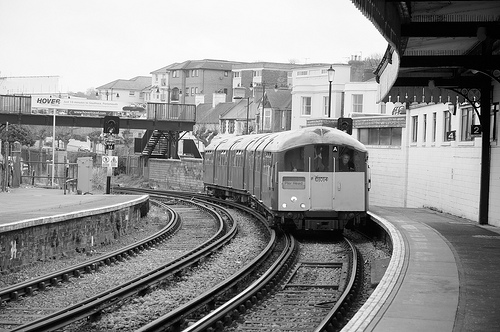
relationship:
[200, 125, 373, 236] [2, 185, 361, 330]
train on track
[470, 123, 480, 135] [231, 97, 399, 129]
number 2 on sign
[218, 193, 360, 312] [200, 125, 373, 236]
gravel under train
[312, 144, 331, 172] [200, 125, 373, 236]
window on train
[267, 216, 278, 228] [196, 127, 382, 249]
wheels on train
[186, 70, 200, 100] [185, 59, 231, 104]
windows on building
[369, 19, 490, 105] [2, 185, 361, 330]
awning over track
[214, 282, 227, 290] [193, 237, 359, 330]
rails on tracks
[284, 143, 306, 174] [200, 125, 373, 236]
window on front of train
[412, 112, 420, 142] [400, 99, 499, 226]
window on side of building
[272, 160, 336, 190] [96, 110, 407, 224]
sign on front of train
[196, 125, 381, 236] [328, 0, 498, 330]
train coming into station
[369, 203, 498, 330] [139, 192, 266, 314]
platform beside tracks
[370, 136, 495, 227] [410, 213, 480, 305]
wall alongside train platform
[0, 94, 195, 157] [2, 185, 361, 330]
bridge over track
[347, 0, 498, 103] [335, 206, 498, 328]
shelter over platform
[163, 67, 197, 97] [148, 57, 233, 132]
windows are on buildings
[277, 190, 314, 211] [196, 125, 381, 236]
lights are on train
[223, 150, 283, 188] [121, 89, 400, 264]
windows are on train.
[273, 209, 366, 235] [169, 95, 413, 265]
wheels are on train.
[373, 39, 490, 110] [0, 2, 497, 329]
awning over station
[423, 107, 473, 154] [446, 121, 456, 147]
sign has 4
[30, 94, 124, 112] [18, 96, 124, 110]
advertisement on sign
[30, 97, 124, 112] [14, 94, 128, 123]
advertisement on sign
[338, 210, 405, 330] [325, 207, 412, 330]
line next to tracks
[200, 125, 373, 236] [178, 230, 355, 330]
train on tracks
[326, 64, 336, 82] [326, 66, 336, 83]
lamp on lamp